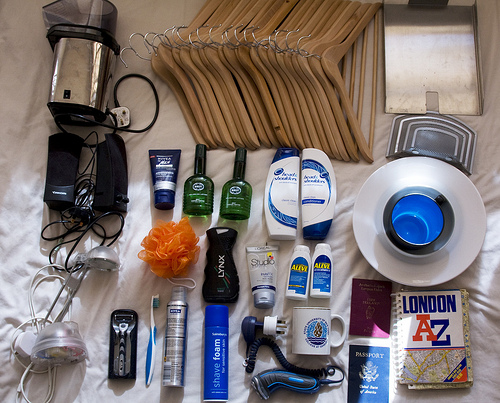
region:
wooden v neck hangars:
[115, 5, 387, 164]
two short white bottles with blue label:
[285, 242, 333, 301]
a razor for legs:
[107, 308, 139, 382]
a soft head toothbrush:
[142, 289, 156, 384]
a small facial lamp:
[10, 244, 121, 401]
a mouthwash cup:
[290, 302, 344, 357]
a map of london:
[392, 290, 480, 392]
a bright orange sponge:
[135, 213, 202, 288]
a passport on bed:
[344, 343, 392, 402]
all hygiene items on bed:
[2, 1, 498, 401]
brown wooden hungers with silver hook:
[143, 17, 388, 134]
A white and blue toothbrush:
[292, 300, 350, 360]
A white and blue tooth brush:
[141, 290, 158, 381]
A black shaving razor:
[115, 302, 142, 390]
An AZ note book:
[389, 291, 475, 401]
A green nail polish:
[229, 149, 254, 226]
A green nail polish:
[187, 144, 220, 224]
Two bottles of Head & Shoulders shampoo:
[267, 153, 329, 235]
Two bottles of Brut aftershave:
[182, 143, 247, 215]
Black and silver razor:
[105, 303, 142, 383]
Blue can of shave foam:
[200, 303, 230, 399]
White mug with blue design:
[289, 308, 339, 356]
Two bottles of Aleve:
[282, 242, 333, 301]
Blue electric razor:
[245, 363, 344, 402]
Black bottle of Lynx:
[198, 224, 237, 300]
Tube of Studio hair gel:
[244, 243, 280, 306]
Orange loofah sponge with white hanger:
[144, 220, 198, 287]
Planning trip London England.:
[390, 264, 484, 398]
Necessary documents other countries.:
[345, 274, 391, 401]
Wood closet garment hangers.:
[137, 2, 392, 137]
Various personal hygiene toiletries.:
[114, 149, 244, 399]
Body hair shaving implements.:
[240, 304, 345, 402]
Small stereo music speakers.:
[39, 127, 139, 233]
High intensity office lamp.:
[29, 247, 116, 389]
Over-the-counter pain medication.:
[282, 246, 342, 305]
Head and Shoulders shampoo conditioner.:
[262, 140, 337, 237]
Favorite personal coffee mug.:
[286, 302, 348, 353]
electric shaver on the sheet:
[245, 369, 341, 400]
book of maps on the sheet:
[399, 290, 471, 393]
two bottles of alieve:
[282, 243, 337, 306]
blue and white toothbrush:
[145, 289, 160, 394]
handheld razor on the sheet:
[103, 309, 135, 385]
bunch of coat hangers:
[126, 5, 371, 153]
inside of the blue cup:
[388, 192, 443, 249]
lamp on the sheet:
[40, 242, 106, 382]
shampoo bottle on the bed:
[202, 225, 239, 302]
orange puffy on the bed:
[135, 211, 196, 288]